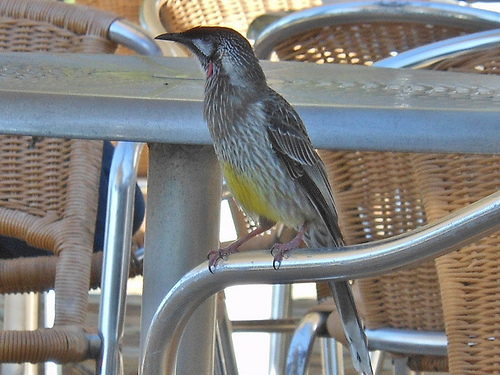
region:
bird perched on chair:
[155, 14, 376, 369]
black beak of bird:
[157, 27, 202, 62]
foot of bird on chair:
[198, 243, 248, 271]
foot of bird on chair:
[263, 242, 302, 264]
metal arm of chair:
[200, 240, 347, 318]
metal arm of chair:
[96, 160, 134, 369]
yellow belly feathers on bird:
[231, 188, 263, 215]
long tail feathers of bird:
[327, 280, 372, 373]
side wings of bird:
[268, 120, 340, 215]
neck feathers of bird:
[198, 87, 237, 132]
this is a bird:
[152, 21, 342, 268]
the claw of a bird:
[267, 240, 295, 277]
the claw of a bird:
[198, 235, 241, 271]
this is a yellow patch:
[225, 150, 277, 236]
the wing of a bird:
[270, 116, 350, 231]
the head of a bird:
[157, 16, 264, 92]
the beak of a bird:
[147, 20, 183, 55]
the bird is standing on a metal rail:
[161, 221, 406, 312]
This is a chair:
[352, 45, 497, 370]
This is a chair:
[1, 5, 148, 358]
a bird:
[187, 20, 385, 327]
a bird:
[131, 43, 293, 291]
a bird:
[193, 51, 313, 258]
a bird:
[151, 3, 453, 202]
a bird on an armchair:
[163, 17, 380, 313]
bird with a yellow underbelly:
[148, 16, 368, 306]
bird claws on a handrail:
[186, 203, 334, 270]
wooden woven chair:
[1, 1, 212, 367]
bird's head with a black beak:
[150, 14, 293, 109]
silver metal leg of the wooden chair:
[78, 15, 144, 357]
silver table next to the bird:
[6, 50, 498, 205]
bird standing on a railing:
[156, 28, 410, 277]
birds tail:
[283, 225, 392, 365]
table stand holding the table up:
[135, 140, 240, 372]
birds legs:
[191, 217, 337, 279]